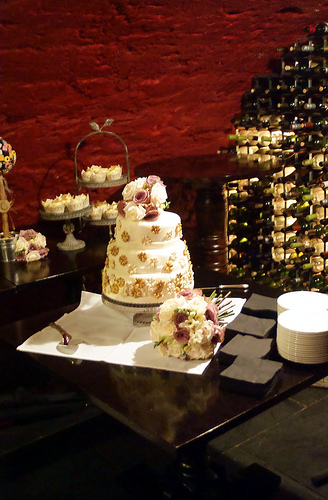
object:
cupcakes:
[40, 164, 123, 221]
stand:
[101, 292, 163, 327]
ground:
[0, 1, 328, 230]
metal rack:
[75, 118, 131, 236]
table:
[0, 276, 328, 455]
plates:
[276, 290, 327, 364]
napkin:
[219, 354, 284, 384]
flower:
[133, 189, 151, 204]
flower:
[150, 182, 168, 207]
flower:
[117, 201, 127, 217]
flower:
[123, 201, 147, 221]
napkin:
[219, 334, 273, 358]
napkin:
[243, 293, 278, 312]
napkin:
[225, 313, 276, 337]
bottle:
[308, 230, 328, 242]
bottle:
[305, 206, 328, 221]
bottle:
[302, 153, 328, 171]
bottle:
[263, 216, 297, 231]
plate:
[277, 310, 328, 334]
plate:
[276, 290, 327, 309]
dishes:
[276, 308, 328, 365]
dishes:
[276, 291, 328, 311]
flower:
[144, 204, 160, 221]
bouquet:
[150, 288, 236, 360]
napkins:
[219, 292, 284, 385]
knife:
[198, 284, 250, 289]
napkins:
[16, 288, 247, 377]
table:
[134, 154, 286, 273]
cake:
[101, 174, 195, 305]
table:
[0, 222, 87, 323]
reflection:
[2, 262, 49, 287]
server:
[48, 320, 85, 347]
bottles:
[218, 23, 328, 292]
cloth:
[16, 291, 247, 377]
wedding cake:
[101, 174, 194, 329]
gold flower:
[141, 235, 152, 247]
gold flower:
[166, 231, 173, 240]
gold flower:
[118, 255, 128, 266]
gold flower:
[116, 277, 125, 288]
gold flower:
[118, 219, 123, 230]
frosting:
[118, 255, 128, 267]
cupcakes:
[40, 192, 89, 214]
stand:
[38, 203, 93, 252]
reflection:
[110, 365, 219, 445]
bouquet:
[117, 175, 171, 220]